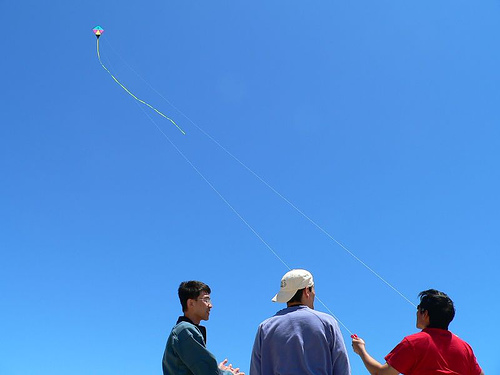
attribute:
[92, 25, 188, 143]
kite — flying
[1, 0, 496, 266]
sky — blue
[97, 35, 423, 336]
main strings — white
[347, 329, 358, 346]
handle — red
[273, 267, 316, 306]
hat — white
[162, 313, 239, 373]
jacket — blue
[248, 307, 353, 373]
shirt — blue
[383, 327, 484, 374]
shirt — red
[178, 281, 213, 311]
hair — short, black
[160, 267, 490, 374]
men — talking